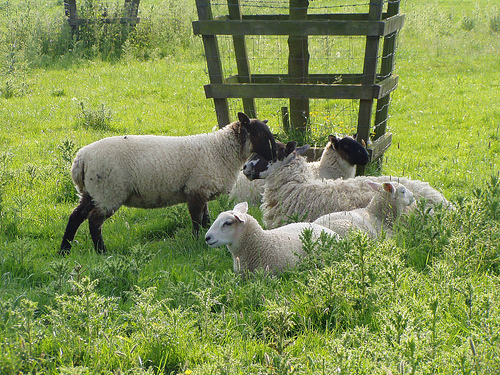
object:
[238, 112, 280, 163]
black headed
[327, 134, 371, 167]
black headed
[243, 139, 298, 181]
black headed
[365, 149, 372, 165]
nose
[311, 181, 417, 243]
sheep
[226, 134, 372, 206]
sheep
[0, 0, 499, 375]
grass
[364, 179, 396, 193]
ears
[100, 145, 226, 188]
handle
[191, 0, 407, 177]
object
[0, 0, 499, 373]
ground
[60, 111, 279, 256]
sheep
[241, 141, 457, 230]
sheep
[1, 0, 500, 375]
farm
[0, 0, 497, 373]
field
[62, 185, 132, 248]
legs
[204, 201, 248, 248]
head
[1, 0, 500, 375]
pasture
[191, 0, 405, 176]
wooden boards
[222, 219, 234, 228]
eye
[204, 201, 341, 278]
closest sheep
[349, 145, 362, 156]
black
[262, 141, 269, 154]
black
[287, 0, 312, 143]
trunk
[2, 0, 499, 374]
sunshine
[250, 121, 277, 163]
face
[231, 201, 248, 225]
ears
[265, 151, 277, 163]
nose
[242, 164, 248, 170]
nose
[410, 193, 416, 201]
nose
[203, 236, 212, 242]
nose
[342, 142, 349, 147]
eye